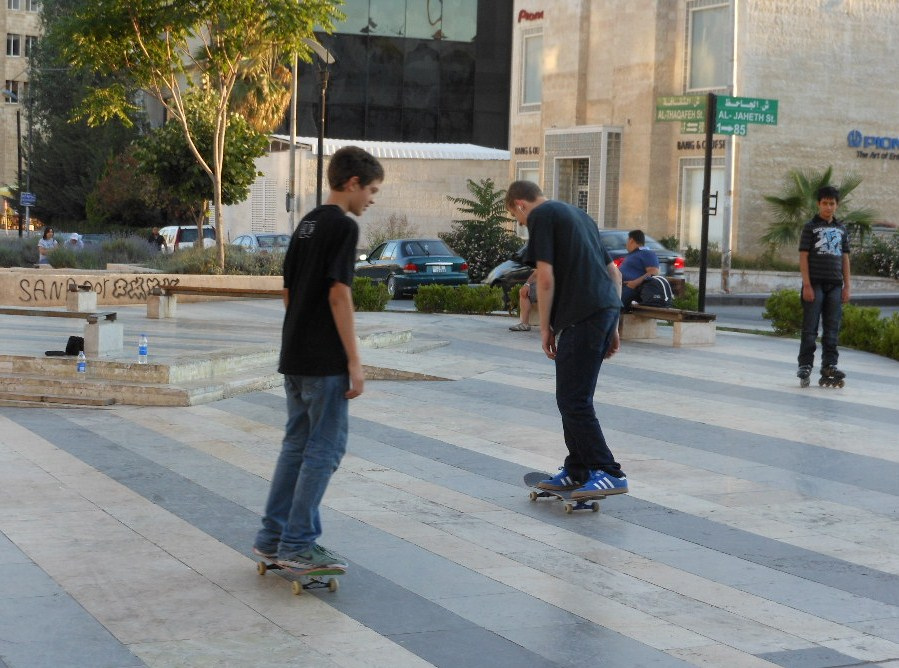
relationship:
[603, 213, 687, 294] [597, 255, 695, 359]
person sitting on a bench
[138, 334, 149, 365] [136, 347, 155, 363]
water bottle with a label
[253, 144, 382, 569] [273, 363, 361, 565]
boy wearing jeans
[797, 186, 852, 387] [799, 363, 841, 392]
boy wearing roller skates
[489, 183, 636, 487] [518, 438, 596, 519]
boy riding skateboard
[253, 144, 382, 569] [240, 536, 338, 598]
boy riding skateboard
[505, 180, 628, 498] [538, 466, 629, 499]
boy wearing shoes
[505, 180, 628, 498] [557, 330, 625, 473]
boy wearing jeans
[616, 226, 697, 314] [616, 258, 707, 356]
boy sitting on a bench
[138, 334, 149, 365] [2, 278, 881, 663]
water bottle on ground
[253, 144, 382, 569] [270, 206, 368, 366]
boy wearing a shirt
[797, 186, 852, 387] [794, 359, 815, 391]
boy wearing rollerskate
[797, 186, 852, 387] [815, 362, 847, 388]
boy wearing rollerskate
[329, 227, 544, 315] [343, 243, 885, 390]
vehicles parked along side of road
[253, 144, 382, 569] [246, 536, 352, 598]
boy on skateboard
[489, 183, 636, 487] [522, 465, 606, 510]
boy on skateboard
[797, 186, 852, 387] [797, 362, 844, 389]
boy on rollerblades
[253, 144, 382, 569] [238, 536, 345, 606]
boy on skateboard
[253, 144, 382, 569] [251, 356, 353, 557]
boy wearing blue jeans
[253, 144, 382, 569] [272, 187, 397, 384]
boy wearing shirt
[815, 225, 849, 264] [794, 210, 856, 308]
print on shirt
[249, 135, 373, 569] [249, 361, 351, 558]
boy on skateboard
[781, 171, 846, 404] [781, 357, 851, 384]
boy wearing rollerblades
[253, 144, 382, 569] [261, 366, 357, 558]
boy wearing blue jeans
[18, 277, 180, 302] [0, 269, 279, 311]
graffiti on wall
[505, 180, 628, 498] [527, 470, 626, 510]
boy riding skateboard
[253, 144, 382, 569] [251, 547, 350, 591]
boy riding skateboard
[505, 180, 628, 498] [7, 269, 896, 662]
boy riding on area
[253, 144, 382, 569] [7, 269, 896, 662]
boy riding on area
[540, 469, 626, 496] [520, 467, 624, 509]
shoes on skateboard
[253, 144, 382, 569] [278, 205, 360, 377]
boy wearing shirt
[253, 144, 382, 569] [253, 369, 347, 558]
boy wearing jeans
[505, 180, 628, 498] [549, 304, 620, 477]
boy wearing jeans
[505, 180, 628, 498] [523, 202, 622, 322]
boy wearing shirt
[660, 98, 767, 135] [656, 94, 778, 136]
lettering on lettering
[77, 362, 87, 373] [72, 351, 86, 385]
labels on water bottle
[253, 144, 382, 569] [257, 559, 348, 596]
boy on skateboard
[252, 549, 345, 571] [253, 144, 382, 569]
shoes on boy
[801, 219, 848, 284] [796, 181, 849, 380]
top on boy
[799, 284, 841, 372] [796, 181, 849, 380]
jeans on boy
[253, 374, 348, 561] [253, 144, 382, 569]
blue jeans on boy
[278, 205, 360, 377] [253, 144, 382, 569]
shirt on boy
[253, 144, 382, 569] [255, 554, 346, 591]
boy on skateboard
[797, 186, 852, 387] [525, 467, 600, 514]
boy on skateboard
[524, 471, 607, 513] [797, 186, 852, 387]
skateboard on boy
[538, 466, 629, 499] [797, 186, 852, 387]
shoes on boy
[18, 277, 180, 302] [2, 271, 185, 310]
graffiti on wall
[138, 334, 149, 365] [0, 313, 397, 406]
water bottle on steps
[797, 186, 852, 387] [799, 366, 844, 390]
boy on rollerblades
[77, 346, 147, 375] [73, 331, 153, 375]
labels on water bottles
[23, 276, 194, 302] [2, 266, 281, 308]
graffiti on wall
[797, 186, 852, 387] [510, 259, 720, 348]
boy on bench